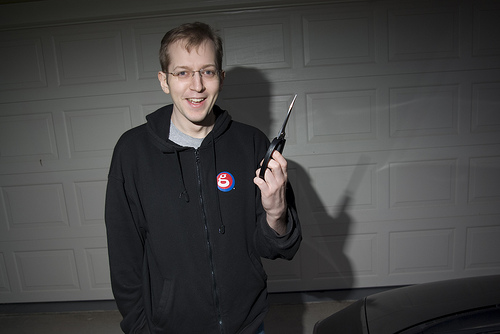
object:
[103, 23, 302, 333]
man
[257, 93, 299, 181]
scissors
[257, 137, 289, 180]
handle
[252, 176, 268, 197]
fingers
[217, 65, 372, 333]
shadow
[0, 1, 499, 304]
garage door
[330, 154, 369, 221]
shadow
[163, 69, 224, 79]
glasses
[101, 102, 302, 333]
hoodie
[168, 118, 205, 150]
shirt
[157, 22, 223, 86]
hair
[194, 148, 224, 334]
zipper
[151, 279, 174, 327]
pocket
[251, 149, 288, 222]
hand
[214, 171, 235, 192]
logo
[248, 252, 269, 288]
pocket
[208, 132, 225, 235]
string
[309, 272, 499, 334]
car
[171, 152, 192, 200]
drawstrings